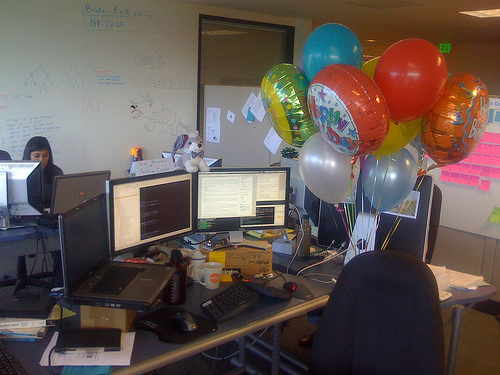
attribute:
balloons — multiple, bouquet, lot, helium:
[258, 22, 492, 213]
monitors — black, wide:
[108, 168, 290, 254]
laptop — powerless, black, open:
[57, 192, 175, 312]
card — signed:
[129, 157, 181, 179]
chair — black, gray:
[309, 249, 453, 373]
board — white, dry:
[0, 0, 199, 178]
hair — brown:
[23, 135, 54, 180]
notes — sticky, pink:
[439, 128, 498, 192]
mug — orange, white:
[195, 260, 222, 290]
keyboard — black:
[202, 280, 261, 327]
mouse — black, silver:
[172, 309, 199, 333]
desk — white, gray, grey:
[0, 234, 351, 374]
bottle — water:
[165, 249, 188, 303]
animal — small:
[171, 130, 213, 173]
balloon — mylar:
[376, 31, 448, 125]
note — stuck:
[479, 178, 493, 192]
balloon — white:
[297, 131, 361, 206]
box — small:
[208, 241, 274, 280]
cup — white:
[186, 254, 206, 283]